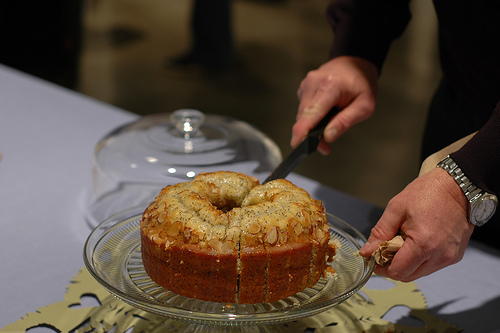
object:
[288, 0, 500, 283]
person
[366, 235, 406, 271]
napkin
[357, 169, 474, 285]
hand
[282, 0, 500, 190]
shirt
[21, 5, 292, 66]
blurried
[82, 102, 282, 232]
lid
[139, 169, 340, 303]
cake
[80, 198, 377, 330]
dish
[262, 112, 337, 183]
knife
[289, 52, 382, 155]
hand